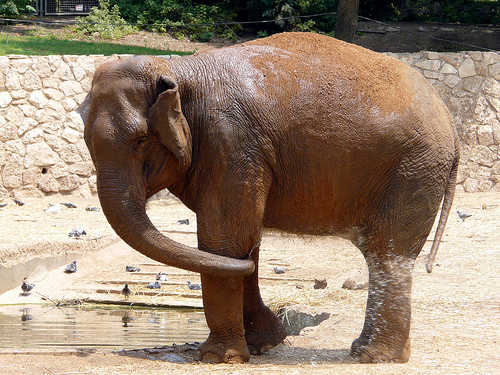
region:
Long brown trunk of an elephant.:
[100, 185, 256, 275]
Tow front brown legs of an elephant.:
[190, 190, 286, 360]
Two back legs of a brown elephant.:
[345, 230, 416, 360]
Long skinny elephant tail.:
[422, 116, 457, 271]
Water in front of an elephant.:
[0, 305, 205, 350]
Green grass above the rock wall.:
[0, 30, 190, 55]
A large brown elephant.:
[75, 27, 460, 362]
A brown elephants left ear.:
[147, 72, 189, 167]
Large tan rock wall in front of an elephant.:
[0, 52, 138, 203]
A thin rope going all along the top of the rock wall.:
[0, 15, 498, 55]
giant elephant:
[77, 28, 460, 367]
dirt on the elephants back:
[247, 36, 409, 123]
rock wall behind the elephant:
[2, 58, 498, 193]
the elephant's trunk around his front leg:
[106, 167, 255, 274]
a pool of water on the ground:
[2, 248, 219, 344]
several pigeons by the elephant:
[18, 260, 200, 304]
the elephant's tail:
[427, 107, 456, 274]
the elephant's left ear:
[148, 78, 186, 155]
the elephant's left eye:
[134, 135, 145, 147]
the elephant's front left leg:
[200, 165, 267, 358]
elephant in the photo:
[0, 37, 486, 344]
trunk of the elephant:
[110, 185, 255, 287]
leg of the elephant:
[167, 162, 269, 347]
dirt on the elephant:
[259, 45, 418, 140]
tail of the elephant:
[401, 124, 482, 292]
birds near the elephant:
[17, 239, 142, 329]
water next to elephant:
[48, 305, 145, 368]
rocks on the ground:
[303, 260, 368, 300]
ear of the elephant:
[135, 70, 214, 161]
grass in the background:
[13, 6, 141, 59]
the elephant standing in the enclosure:
[75, 30, 461, 365]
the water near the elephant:
[0, 299, 209, 349]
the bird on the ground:
[455, 208, 472, 221]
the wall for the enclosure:
[0, 49, 497, 201]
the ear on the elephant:
[148, 76, 192, 169]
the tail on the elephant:
[425, 100, 460, 272]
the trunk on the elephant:
[95, 161, 255, 274]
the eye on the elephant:
[133, 134, 145, 148]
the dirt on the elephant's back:
[223, 30, 413, 117]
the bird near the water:
[19, 276, 35, 294]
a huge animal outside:
[76, 33, 464, 366]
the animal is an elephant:
[71, 23, 459, 362]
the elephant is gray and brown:
[74, 30, 461, 368]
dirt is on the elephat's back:
[218, 33, 425, 122]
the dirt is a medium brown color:
[234, 25, 409, 112]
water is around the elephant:
[3, 247, 302, 363]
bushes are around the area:
[5, 5, 342, 50]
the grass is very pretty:
[7, 30, 202, 55]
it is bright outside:
[5, 2, 495, 360]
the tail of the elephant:
[425, 115, 467, 277]